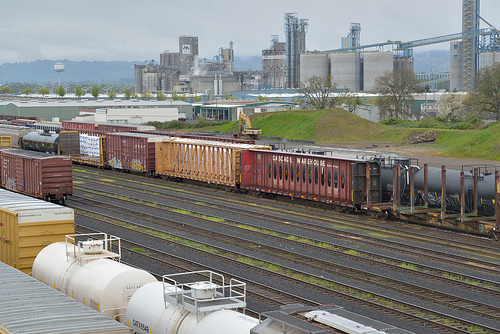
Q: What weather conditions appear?
A: It is cloudy.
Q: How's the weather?
A: It is cloudy.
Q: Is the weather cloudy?
A: Yes, it is cloudy.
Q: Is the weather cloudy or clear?
A: It is cloudy.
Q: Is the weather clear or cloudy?
A: It is cloudy.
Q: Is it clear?
A: No, it is cloudy.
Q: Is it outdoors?
A: Yes, it is outdoors.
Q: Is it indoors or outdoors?
A: It is outdoors.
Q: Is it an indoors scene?
A: No, it is outdoors.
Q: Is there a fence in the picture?
A: No, there are no fences.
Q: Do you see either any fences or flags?
A: No, there are no fences or flags.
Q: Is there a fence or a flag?
A: No, there are no fences or flags.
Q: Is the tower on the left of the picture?
A: Yes, the tower is on the left of the image.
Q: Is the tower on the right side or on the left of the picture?
A: The tower is on the left of the image.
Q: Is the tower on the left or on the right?
A: The tower is on the left of the image.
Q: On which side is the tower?
A: The tower is on the left of the image.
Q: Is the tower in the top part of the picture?
A: Yes, the tower is in the top of the image.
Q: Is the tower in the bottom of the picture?
A: No, the tower is in the top of the image.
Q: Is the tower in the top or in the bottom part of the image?
A: The tower is in the top of the image.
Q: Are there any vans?
A: No, there are no vans.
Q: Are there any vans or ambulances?
A: No, there are no vans or ambulances.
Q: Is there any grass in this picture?
A: Yes, there is grass.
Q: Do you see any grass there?
A: Yes, there is grass.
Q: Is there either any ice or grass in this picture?
A: Yes, there is grass.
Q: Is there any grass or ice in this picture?
A: Yes, there is grass.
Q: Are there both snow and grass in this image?
A: No, there is grass but no snow.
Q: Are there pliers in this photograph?
A: No, there are no pliers.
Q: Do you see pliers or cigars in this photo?
A: No, there are no pliers or cigars.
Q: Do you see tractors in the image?
A: No, there are no tractors.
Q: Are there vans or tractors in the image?
A: No, there are no tractors or vans.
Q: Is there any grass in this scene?
A: Yes, there is grass.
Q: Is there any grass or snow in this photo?
A: Yes, there is grass.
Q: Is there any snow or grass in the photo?
A: Yes, there is grass.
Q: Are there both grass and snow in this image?
A: No, there is grass but no snow.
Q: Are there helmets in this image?
A: No, there are no helmets.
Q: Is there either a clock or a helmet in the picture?
A: No, there are no helmets or clocks.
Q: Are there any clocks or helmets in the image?
A: No, there are no helmets or clocks.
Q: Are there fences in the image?
A: No, there are no fences.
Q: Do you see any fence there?
A: No, there are no fences.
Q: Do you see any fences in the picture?
A: No, there are no fences.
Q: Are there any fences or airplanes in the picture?
A: No, there are no fences or airplanes.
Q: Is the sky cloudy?
A: Yes, the sky is cloudy.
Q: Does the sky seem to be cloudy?
A: Yes, the sky is cloudy.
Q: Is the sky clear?
A: No, the sky is cloudy.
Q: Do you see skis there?
A: No, there are no skis.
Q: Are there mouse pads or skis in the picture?
A: No, there are no skis or mouse pads.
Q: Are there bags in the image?
A: No, there are no bags.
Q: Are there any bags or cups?
A: No, there are no bags or cups.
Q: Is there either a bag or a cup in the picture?
A: No, there are no bags or cups.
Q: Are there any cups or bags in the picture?
A: No, there are no bags or cups.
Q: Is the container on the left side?
A: Yes, the container is on the left of the image.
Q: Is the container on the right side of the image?
A: No, the container is on the left of the image.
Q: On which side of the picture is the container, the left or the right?
A: The container is on the left of the image.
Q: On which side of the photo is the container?
A: The container is on the left of the image.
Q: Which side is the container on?
A: The container is on the left of the image.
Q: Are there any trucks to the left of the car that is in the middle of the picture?
A: No, there is a container to the left of the car.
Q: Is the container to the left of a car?
A: Yes, the container is to the left of a car.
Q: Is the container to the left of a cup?
A: No, the container is to the left of a car.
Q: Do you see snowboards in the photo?
A: No, there are no snowboards.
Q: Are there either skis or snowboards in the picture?
A: No, there are no snowboards or skis.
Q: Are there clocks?
A: No, there are no clocks.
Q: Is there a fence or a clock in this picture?
A: No, there are no clocks or fences.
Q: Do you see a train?
A: Yes, there is a train.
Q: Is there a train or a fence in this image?
A: Yes, there is a train.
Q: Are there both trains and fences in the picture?
A: No, there is a train but no fences.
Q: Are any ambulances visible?
A: No, there are no ambulances.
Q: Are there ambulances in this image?
A: No, there are no ambulances.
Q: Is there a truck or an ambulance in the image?
A: No, there are no ambulances or trucks.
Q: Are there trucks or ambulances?
A: No, there are no ambulances or trucks.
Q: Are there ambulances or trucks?
A: No, there are no ambulances or trucks.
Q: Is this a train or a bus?
A: This is a train.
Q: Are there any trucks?
A: No, there are no trucks.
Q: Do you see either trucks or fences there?
A: No, there are no trucks or fences.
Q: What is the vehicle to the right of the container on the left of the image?
A: The vehicle is a car.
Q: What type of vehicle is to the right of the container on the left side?
A: The vehicle is a car.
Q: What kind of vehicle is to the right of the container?
A: The vehicle is a car.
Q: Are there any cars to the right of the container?
A: Yes, there is a car to the right of the container.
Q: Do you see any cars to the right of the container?
A: Yes, there is a car to the right of the container.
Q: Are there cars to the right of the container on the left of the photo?
A: Yes, there is a car to the right of the container.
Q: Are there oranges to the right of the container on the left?
A: No, there is a car to the right of the container.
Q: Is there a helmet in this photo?
A: No, there are no helmets.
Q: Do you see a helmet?
A: No, there are no helmets.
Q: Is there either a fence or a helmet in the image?
A: No, there are no helmets or fences.